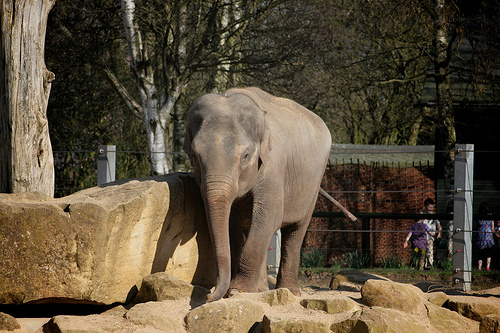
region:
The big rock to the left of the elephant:
[14, 175, 244, 291]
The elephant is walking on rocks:
[56, 275, 498, 330]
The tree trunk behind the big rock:
[6, 85, 76, 196]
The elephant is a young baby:
[187, 87, 344, 304]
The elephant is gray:
[165, 87, 351, 299]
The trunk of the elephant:
[195, 185, 245, 306]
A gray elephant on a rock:
[187, 85, 332, 306]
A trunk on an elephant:
[190, 188, 237, 301]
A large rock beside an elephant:
[2, 170, 203, 302]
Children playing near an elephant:
[402, 201, 439, 266]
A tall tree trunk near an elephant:
[2, 3, 57, 192]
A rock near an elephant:
[358, 277, 420, 315]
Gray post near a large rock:
[93, 145, 120, 185]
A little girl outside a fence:
[472, 212, 494, 268]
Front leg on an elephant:
[232, 213, 271, 297]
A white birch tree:
[107, 0, 213, 167]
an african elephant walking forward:
[183, 88, 331, 300]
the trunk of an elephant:
[199, 175, 239, 300]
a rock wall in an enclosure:
[1, 172, 232, 307]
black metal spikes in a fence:
[296, 156, 450, 272]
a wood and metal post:
[452, 143, 471, 292]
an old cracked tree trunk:
[2, 3, 56, 203]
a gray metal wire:
[106, 147, 190, 156]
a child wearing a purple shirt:
[402, 215, 437, 271]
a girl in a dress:
[472, 201, 497, 271]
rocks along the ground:
[0, 267, 499, 331]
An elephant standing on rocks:
[188, 75, 349, 297]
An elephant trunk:
[197, 192, 252, 299]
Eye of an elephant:
[237, 137, 254, 172]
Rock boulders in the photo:
[260, 277, 426, 330]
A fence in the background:
[332, 162, 419, 252]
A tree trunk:
[105, 69, 183, 169]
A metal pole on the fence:
[445, 142, 480, 271]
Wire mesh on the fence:
[349, 167, 429, 263]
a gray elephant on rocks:
[178, 87, 335, 294]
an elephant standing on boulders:
[180, 81, 337, 326]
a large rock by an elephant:
[1, 83, 332, 310]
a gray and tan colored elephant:
[188, 83, 332, 300]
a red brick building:
[291, 142, 436, 265]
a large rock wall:
[0, 169, 253, 308]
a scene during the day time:
[10, 15, 488, 330]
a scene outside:
[13, 6, 475, 331]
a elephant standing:
[169, 68, 346, 318]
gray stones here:
[0, 159, 491, 322]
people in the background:
[404, 182, 499, 286]